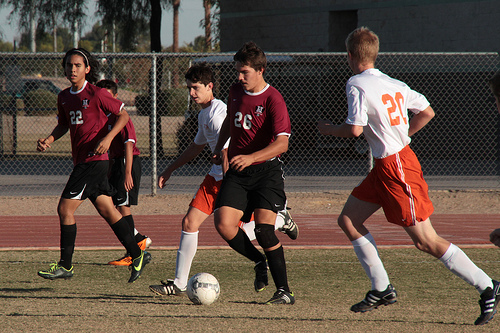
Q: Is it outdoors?
A: Yes, it is outdoors.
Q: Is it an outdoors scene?
A: Yes, it is outdoors.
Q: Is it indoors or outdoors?
A: It is outdoors.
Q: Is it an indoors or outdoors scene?
A: It is outdoors.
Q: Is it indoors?
A: No, it is outdoors.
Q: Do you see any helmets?
A: No, there are no helmets.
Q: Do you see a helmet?
A: No, there are no helmets.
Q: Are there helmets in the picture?
A: No, there are no helmets.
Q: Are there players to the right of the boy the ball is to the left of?
A: Yes, there is a player to the right of the boy.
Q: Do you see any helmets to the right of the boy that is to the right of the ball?
A: No, there is a player to the right of the boy.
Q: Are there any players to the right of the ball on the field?
A: Yes, there is a player to the right of the ball.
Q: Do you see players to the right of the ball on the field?
A: Yes, there is a player to the right of the ball.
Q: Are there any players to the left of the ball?
A: No, the player is to the right of the ball.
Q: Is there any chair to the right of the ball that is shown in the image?
A: No, there is a player to the right of the ball.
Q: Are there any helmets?
A: No, there are no helmets.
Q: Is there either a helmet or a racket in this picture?
A: No, there are no helmets or rackets.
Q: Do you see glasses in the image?
A: No, there are no glasses.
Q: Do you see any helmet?
A: No, there are no helmets.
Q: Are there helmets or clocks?
A: No, there are no helmets or clocks.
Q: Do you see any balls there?
A: Yes, there is a ball.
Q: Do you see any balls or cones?
A: Yes, there is a ball.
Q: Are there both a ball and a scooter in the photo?
A: No, there is a ball but no scooters.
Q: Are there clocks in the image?
A: No, there are no clocks.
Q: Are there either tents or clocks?
A: No, there are no clocks or tents.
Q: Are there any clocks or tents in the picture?
A: No, there are no clocks or tents.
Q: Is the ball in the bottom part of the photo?
A: Yes, the ball is in the bottom of the image.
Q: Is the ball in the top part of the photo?
A: No, the ball is in the bottom of the image.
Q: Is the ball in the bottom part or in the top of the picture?
A: The ball is in the bottom of the image.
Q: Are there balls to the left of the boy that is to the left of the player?
A: Yes, there is a ball to the left of the boy.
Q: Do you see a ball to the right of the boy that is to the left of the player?
A: No, the ball is to the left of the boy.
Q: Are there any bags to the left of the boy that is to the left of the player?
A: No, there is a ball to the left of the boy.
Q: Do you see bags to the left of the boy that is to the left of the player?
A: No, there is a ball to the left of the boy.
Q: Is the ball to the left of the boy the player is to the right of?
A: Yes, the ball is to the left of the boy.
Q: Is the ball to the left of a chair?
A: No, the ball is to the left of the boy.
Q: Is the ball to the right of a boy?
A: No, the ball is to the left of a boy.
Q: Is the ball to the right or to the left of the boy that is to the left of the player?
A: The ball is to the left of the boy.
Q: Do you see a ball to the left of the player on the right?
A: Yes, there is a ball to the left of the player.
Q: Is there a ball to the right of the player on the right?
A: No, the ball is to the left of the player.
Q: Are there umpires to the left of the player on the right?
A: No, there is a ball to the left of the player.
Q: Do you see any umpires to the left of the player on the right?
A: No, there is a ball to the left of the player.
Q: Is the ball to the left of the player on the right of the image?
A: Yes, the ball is to the left of the player.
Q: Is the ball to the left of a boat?
A: No, the ball is to the left of the player.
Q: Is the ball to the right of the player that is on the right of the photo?
A: No, the ball is to the left of the player.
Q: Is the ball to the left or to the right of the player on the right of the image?
A: The ball is to the left of the player.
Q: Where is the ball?
A: The ball is on the field.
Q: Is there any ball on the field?
A: Yes, there is a ball on the field.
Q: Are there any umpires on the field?
A: No, there is a ball on the field.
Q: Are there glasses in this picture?
A: No, there are no glasses.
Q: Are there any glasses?
A: No, there are no glasses.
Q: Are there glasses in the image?
A: No, there are no glasses.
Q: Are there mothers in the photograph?
A: No, there are no mothers.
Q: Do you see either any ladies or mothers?
A: No, there are no mothers or ladies.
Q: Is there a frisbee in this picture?
A: No, there are no frisbees.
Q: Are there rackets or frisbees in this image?
A: No, there are no frisbees or rackets.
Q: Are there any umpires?
A: No, there are no umpires.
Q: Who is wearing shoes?
A: The player is wearing shoes.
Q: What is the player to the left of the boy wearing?
A: The player is wearing shoes.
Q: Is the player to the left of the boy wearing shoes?
A: Yes, the player is wearing shoes.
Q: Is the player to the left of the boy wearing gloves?
A: No, the player is wearing shoes.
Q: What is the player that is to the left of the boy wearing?
A: The player is wearing shoes.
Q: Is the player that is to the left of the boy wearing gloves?
A: No, the player is wearing shoes.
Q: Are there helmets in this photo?
A: No, there are no helmets.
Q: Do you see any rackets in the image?
A: No, there are no rackets.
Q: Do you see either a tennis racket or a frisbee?
A: No, there are no rackets or frisbees.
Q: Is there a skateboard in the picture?
A: No, there are no skateboards.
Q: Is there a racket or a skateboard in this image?
A: No, there are no skateboards or rackets.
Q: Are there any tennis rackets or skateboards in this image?
A: No, there are no skateboards or tennis rackets.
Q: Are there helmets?
A: No, there are no helmets.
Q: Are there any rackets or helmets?
A: No, there are no helmets or rackets.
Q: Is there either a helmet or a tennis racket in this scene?
A: No, there are no helmets or rackets.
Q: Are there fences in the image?
A: Yes, there is a fence.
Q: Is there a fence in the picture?
A: Yes, there is a fence.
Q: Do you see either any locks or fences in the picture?
A: Yes, there is a fence.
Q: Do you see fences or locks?
A: Yes, there is a fence.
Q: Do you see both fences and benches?
A: No, there is a fence but no benches.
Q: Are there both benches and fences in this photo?
A: No, there is a fence but no benches.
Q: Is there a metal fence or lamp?
A: Yes, there is a metal fence.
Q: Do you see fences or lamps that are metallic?
A: Yes, the fence is metallic.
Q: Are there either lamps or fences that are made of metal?
A: Yes, the fence is made of metal.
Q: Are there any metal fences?
A: Yes, there is a metal fence.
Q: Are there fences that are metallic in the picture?
A: Yes, there is a metal fence.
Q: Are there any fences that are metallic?
A: Yes, there is a fence that is metallic.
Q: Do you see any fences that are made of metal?
A: Yes, there is a fence that is made of metal.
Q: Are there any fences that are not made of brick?
A: Yes, there is a fence that is made of metal.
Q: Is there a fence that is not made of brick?
A: Yes, there is a fence that is made of metal.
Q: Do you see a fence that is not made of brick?
A: Yes, there is a fence that is made of metal.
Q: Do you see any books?
A: No, there are no books.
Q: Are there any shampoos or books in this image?
A: No, there are no books or shampoos.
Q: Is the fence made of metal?
A: Yes, the fence is made of metal.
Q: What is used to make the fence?
A: The fence is made of metal.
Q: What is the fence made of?
A: The fence is made of metal.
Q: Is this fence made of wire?
A: No, the fence is made of metal.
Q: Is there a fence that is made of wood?
A: No, there is a fence but it is made of metal.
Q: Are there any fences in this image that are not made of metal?
A: No, there is a fence but it is made of metal.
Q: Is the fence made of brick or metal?
A: The fence is made of metal.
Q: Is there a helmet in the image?
A: No, there are no helmets.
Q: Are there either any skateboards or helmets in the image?
A: No, there are no helmets or skateboards.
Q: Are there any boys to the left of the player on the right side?
A: Yes, there is a boy to the left of the player.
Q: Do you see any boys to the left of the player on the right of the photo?
A: Yes, there is a boy to the left of the player.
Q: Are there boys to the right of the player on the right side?
A: No, the boy is to the left of the player.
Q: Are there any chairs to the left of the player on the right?
A: No, there is a boy to the left of the player.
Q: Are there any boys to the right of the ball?
A: Yes, there is a boy to the right of the ball.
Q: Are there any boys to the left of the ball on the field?
A: No, the boy is to the right of the ball.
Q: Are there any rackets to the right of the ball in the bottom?
A: No, there is a boy to the right of the ball.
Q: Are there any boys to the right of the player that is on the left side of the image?
A: Yes, there is a boy to the right of the player.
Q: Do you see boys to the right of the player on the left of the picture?
A: Yes, there is a boy to the right of the player.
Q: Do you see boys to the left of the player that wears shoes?
A: No, the boy is to the right of the player.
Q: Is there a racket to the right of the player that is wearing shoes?
A: No, there is a boy to the right of the player.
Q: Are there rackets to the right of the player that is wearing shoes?
A: No, there is a boy to the right of the player.